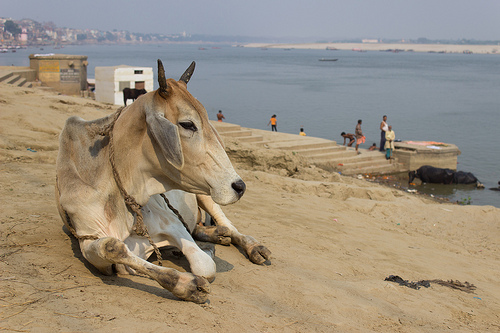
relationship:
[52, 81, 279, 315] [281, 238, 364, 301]
cow lays in sand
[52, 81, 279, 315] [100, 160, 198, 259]
cow has rope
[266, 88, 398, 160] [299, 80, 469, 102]
people are by water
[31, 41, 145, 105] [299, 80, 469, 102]
buildings are beside water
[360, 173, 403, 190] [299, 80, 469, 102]
garbage in water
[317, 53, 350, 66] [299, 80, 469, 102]
boat in water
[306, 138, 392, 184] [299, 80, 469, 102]
stairs are near water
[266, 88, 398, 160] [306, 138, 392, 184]
people are on steps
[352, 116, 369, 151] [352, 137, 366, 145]
person has orange shorts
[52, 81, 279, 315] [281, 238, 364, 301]
cow lying on sand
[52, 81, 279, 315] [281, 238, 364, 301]
animal laying on sand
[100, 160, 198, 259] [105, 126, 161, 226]
rope around neck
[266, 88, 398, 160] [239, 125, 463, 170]
people are on dock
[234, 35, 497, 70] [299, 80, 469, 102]
object in water